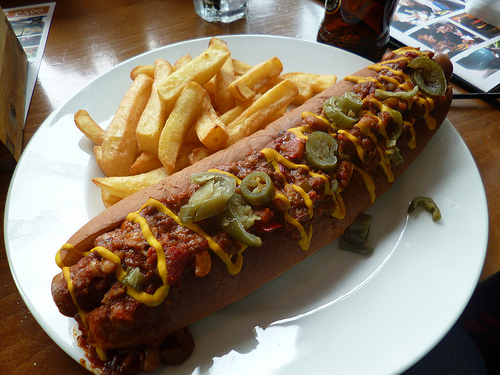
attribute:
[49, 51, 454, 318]
hot dog — long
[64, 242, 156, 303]
stream — small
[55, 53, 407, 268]
bun — brown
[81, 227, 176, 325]
sauce — red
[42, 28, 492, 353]
table — wooden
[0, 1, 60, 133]
paper — small, white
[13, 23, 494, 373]
plate — white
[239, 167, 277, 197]
pepper — green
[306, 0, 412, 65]
bottle — brown, beverage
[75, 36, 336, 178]
pile — big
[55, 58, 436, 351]
mustard — yellow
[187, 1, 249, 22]
glass — clear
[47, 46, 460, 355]
roll — hot dog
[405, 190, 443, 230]
slice — jalepeno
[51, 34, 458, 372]
hot dog — long